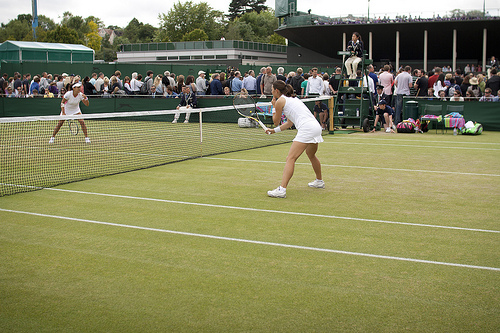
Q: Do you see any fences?
A: No, there are no fences.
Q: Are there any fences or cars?
A: No, there are no fences or cars.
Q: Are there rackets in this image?
A: Yes, there is a racket.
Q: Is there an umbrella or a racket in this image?
A: Yes, there is a racket.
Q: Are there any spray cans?
A: No, there are no spray cans.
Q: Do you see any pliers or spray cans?
A: No, there are no spray cans or pliers.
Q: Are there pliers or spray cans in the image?
A: No, there are no spray cans or pliers.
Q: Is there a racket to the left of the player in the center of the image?
A: Yes, there is a racket to the left of the player.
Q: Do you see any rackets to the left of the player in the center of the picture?
A: Yes, there is a racket to the left of the player.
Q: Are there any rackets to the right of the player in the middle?
A: No, the racket is to the left of the player.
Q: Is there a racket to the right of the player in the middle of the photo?
A: No, the racket is to the left of the player.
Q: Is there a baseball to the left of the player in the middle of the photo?
A: No, there is a racket to the left of the player.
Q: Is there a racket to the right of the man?
A: Yes, there is a racket to the right of the man.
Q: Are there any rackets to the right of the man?
A: Yes, there is a racket to the right of the man.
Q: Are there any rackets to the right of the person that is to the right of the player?
A: Yes, there is a racket to the right of the man.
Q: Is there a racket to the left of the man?
A: No, the racket is to the right of the man.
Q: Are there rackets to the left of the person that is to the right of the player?
A: No, the racket is to the right of the man.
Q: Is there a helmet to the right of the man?
A: No, there is a racket to the right of the man.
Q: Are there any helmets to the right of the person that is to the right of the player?
A: No, there is a racket to the right of the man.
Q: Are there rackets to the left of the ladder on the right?
A: Yes, there is a racket to the left of the ladder.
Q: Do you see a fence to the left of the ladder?
A: No, there is a racket to the left of the ladder.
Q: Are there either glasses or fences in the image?
A: No, there are no fences or glasses.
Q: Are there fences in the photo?
A: No, there are no fences.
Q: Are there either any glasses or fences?
A: No, there are no fences or glasses.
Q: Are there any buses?
A: No, there are no buses.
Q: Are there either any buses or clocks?
A: No, there are no buses or clocks.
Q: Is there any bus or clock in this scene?
A: No, there are no buses or clocks.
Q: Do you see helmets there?
A: No, there are no helmets.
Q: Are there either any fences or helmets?
A: No, there are no helmets or fences.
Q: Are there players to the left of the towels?
A: Yes, there are players to the left of the towels.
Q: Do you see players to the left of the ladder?
A: Yes, there are players to the left of the ladder.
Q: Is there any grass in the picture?
A: Yes, there is grass.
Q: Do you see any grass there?
A: Yes, there is grass.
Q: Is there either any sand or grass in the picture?
A: Yes, there is grass.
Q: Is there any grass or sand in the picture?
A: Yes, there is grass.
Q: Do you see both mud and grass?
A: No, there is grass but no mud.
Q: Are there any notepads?
A: No, there are no notepads.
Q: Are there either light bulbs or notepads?
A: No, there are no notepads or light bulbs.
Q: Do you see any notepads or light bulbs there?
A: No, there are no notepads or light bulbs.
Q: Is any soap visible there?
A: No, there are no soaps.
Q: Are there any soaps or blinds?
A: No, there are no soaps or blinds.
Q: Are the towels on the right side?
A: Yes, the towels are on the right of the image.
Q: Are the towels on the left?
A: No, the towels are on the right of the image.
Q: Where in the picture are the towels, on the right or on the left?
A: The towels are on the right of the image.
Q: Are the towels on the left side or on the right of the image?
A: The towels are on the right of the image.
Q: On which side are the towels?
A: The towels are on the right of the image.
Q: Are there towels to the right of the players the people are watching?
A: Yes, there are towels to the right of the players.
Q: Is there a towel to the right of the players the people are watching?
A: Yes, there are towels to the right of the players.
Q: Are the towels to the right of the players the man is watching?
A: Yes, the towels are to the right of the players.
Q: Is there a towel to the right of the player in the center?
A: Yes, there are towels to the right of the player.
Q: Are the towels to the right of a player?
A: Yes, the towels are to the right of a player.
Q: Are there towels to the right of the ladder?
A: Yes, there are towels to the right of the ladder.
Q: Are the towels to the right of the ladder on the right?
A: Yes, the towels are to the right of the ladder.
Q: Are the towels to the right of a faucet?
A: No, the towels are to the right of the ladder.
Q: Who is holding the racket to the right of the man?
A: The player is holding the tennis racket.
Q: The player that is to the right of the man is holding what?
A: The player is holding the tennis racket.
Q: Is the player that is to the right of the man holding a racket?
A: Yes, the player is holding a racket.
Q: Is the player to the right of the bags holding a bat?
A: No, the player is holding a racket.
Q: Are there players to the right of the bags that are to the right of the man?
A: Yes, there is a player to the right of the bags.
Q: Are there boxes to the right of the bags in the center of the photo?
A: No, there is a player to the right of the bags.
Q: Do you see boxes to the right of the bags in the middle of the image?
A: No, there is a player to the right of the bags.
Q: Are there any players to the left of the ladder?
A: Yes, there is a player to the left of the ladder.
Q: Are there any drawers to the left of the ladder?
A: No, there is a player to the left of the ladder.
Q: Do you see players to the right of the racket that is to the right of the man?
A: Yes, there is a player to the right of the tennis racket.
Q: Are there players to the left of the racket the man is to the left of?
A: No, the player is to the right of the tennis racket.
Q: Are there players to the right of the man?
A: Yes, there is a player to the right of the man.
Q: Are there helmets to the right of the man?
A: No, there is a player to the right of the man.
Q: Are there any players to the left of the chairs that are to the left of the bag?
A: Yes, there is a player to the left of the chairs.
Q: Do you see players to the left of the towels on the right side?
A: Yes, there is a player to the left of the towels.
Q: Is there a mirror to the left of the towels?
A: No, there is a player to the left of the towels.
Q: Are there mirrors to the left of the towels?
A: No, there is a player to the left of the towels.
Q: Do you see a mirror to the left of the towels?
A: No, there is a player to the left of the towels.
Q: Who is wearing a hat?
A: The player is wearing a hat.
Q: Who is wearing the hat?
A: The player is wearing a hat.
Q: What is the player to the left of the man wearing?
A: The player is wearing a hat.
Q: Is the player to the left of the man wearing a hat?
A: Yes, the player is wearing a hat.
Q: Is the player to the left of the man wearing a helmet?
A: No, the player is wearing a hat.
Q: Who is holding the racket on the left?
A: The player is holding the racket.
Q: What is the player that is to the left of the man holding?
A: The player is holding the racket.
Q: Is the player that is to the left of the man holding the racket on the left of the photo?
A: Yes, the player is holding the racket.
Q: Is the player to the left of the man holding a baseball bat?
A: No, the player is holding the racket.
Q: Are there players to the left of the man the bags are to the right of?
A: Yes, there is a player to the left of the man.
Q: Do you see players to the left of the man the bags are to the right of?
A: Yes, there is a player to the left of the man.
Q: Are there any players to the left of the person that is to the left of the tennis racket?
A: Yes, there is a player to the left of the man.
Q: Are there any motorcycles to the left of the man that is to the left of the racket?
A: No, there is a player to the left of the man.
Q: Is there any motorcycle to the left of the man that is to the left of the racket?
A: No, there is a player to the left of the man.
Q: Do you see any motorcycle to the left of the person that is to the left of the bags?
A: No, there is a player to the left of the man.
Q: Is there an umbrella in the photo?
A: No, there are no umbrellas.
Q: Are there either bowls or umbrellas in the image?
A: No, there are no umbrellas or bowls.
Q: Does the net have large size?
A: Yes, the net is large.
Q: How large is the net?
A: The net is large.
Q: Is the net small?
A: No, the net is large.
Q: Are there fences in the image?
A: No, there are no fences.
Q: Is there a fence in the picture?
A: No, there are no fences.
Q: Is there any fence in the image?
A: No, there are no fences.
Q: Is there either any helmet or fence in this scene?
A: No, there are no fences or helmets.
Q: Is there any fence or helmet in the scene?
A: No, there are no fences or helmets.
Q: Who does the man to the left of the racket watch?
A: The man watches the players.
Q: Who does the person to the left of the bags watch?
A: The man watches the players.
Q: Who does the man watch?
A: The man watches the players.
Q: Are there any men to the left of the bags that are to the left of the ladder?
A: Yes, there is a man to the left of the bags.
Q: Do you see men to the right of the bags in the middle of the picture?
A: No, the man is to the left of the bags.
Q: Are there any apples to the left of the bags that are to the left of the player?
A: No, there is a man to the left of the bags.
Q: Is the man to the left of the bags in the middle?
A: Yes, the man is to the left of the bags.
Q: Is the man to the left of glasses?
A: No, the man is to the left of the bags.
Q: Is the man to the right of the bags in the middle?
A: No, the man is to the left of the bags.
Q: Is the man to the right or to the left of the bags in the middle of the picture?
A: The man is to the left of the bags.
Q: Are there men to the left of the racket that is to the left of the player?
A: Yes, there is a man to the left of the tennis racket.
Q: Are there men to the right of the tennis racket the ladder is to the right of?
A: No, the man is to the left of the tennis racket.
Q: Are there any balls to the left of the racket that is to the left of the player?
A: No, there is a man to the left of the racket.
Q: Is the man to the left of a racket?
A: Yes, the man is to the left of a racket.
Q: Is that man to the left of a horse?
A: No, the man is to the left of a racket.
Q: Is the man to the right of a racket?
A: No, the man is to the left of a racket.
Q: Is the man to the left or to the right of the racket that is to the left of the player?
A: The man is to the left of the tennis racket.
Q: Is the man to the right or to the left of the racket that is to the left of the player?
A: The man is to the left of the tennis racket.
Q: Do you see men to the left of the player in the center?
A: Yes, there is a man to the left of the player.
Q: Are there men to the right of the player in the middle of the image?
A: No, the man is to the left of the player.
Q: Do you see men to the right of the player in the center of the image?
A: No, the man is to the left of the player.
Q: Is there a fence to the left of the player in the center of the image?
A: No, there is a man to the left of the player.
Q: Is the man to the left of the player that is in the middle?
A: Yes, the man is to the left of the player.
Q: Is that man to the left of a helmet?
A: No, the man is to the left of the player.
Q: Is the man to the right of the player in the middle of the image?
A: No, the man is to the left of the player.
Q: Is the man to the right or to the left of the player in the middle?
A: The man is to the left of the player.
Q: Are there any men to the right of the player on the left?
A: Yes, there is a man to the right of the player.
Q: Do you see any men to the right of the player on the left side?
A: Yes, there is a man to the right of the player.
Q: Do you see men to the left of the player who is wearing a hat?
A: No, the man is to the right of the player.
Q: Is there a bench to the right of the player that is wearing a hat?
A: No, there is a man to the right of the player.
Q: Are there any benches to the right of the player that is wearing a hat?
A: No, there is a man to the right of the player.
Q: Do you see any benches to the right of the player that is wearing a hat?
A: No, there is a man to the right of the player.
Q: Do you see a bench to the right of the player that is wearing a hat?
A: No, there is a man to the right of the player.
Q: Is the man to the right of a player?
A: Yes, the man is to the right of a player.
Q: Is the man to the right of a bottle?
A: No, the man is to the right of a player.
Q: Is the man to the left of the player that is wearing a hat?
A: No, the man is to the right of the player.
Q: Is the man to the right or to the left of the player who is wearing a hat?
A: The man is to the right of the player.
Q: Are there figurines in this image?
A: No, there are no figurines.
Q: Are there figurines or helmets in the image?
A: No, there are no figurines or helmets.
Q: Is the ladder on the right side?
A: Yes, the ladder is on the right of the image.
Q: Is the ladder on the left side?
A: No, the ladder is on the right of the image.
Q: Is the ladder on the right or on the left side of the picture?
A: The ladder is on the right of the image.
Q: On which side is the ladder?
A: The ladder is on the right of the image.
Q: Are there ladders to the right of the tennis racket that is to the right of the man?
A: Yes, there is a ladder to the right of the tennis racket.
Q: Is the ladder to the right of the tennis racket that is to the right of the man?
A: Yes, the ladder is to the right of the racket.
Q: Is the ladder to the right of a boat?
A: No, the ladder is to the right of the racket.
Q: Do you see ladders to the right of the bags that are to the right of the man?
A: Yes, there is a ladder to the right of the bags.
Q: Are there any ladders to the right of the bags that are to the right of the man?
A: Yes, there is a ladder to the right of the bags.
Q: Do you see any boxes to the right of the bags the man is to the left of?
A: No, there is a ladder to the right of the bags.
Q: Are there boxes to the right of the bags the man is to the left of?
A: No, there is a ladder to the right of the bags.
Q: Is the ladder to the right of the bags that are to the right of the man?
A: Yes, the ladder is to the right of the bags.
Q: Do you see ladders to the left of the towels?
A: Yes, there is a ladder to the left of the towels.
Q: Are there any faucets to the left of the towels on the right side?
A: No, there is a ladder to the left of the towels.